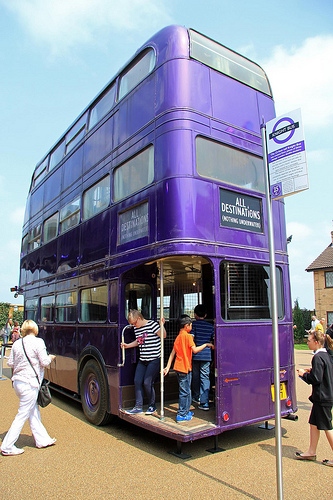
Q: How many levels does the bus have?
A: 3.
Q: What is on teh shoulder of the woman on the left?
A: A purse.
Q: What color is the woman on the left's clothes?
A: White.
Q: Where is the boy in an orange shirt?
A: On the bus.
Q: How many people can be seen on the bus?
A: 3.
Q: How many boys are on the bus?
A: Two.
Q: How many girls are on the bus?
A: One.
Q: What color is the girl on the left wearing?
A: Black.